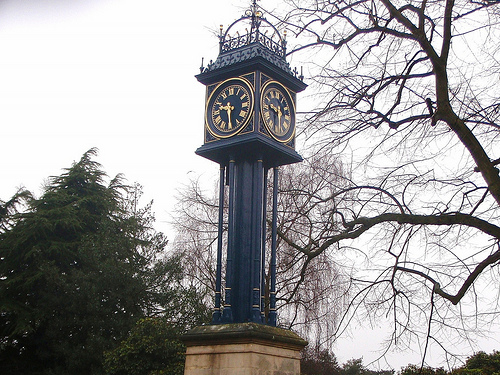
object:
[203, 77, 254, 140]
clock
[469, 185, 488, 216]
branch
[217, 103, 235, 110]
hour hand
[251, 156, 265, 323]
pole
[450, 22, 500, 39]
branch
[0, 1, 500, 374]
sky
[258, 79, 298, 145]
clock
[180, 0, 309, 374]
clock tower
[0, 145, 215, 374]
tree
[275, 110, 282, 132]
hand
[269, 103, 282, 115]
hand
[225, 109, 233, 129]
hand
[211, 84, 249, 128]
face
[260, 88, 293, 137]
face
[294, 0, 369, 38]
branches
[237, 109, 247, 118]
numerals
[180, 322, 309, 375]
base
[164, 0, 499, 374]
tree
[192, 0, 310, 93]
top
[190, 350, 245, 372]
part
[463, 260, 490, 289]
part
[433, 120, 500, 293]
part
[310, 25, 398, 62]
part